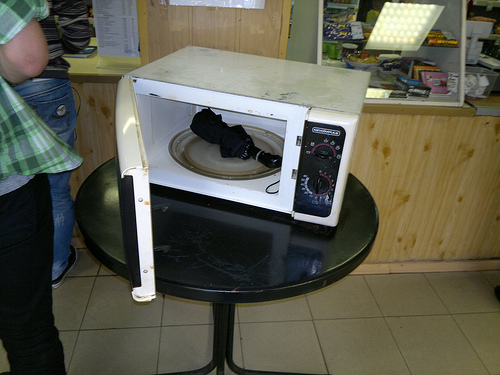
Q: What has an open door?
A: The microwave.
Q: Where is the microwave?
A: On the table.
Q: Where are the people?
A: Next to the table.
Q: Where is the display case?
A: On the counter.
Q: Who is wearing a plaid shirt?
A: The person in front.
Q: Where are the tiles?
A: On the floor.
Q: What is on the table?
A: The microwave.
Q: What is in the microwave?
A: An umbrella.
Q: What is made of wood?
A: The wall and counter.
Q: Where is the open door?
A: On the microwave.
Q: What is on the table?
A: An old microwave with an umbrella in it.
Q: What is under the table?
A: Tile.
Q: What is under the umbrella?
A: A glass microwave tray.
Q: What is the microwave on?
A: A black wooden table.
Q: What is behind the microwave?
A: A glass display case.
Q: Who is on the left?
A: A person in a grey striped shirt.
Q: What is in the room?
A: Microove.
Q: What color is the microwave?
A: White and black.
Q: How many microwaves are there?
A: One.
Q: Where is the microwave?
A: On the table.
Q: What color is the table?
A: Black.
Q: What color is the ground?
A: Gray.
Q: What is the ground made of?
A: Tile.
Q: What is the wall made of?
A: Wood.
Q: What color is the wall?
A: Brown.